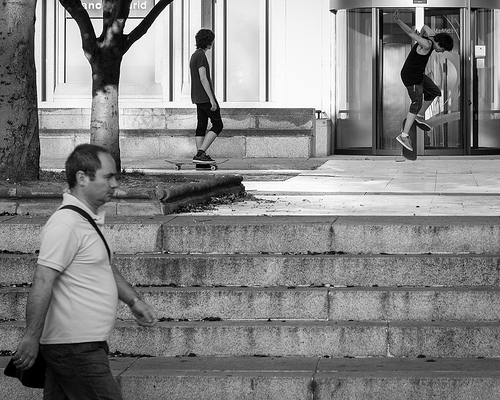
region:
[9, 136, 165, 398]
man in shirt is walking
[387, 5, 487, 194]
boy is jumping in front of door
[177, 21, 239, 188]
boy has one foot on skateboard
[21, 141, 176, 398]
man walking in front of tree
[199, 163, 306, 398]
steps up to sidewalk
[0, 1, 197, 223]
two trees in planter on sidewalk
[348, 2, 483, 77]
boy swinging arms behind him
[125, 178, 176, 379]
watch is on wrist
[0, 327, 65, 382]
ring on right hand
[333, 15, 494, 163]
revolving door into building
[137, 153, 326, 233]
leaves and dirt on sidewalk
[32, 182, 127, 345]
The light colored polo shirt the man is wearing.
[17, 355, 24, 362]
The ring on the man's finger.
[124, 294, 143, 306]
The watch on the man's wrist.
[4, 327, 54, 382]
The messenger bag behind the man's back.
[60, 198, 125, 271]
The messenger bag's strap across the man's chest.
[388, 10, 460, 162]
The boy jumping on the skateboard.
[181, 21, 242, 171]
The boy standing on the skateboard.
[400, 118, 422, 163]
The skateboard the boy is jumping off of.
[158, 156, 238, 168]
The skateboard the boy is standing on.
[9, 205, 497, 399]
The stairs leading up to where the skateboarders are.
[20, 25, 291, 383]
stairs separating two people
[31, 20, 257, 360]
teenager higher than man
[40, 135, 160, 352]
man carrying bag on shoulder strap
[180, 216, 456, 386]
blurred and dark markings on steps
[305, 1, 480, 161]
boy jumping with skateboard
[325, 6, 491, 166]
boy in front of revolving door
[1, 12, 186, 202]
trees growing in front of building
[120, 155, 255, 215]
corners of planting area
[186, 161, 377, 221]
dirt spilling over rim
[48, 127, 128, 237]
man with receding hairline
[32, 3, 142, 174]
A trunk of a tree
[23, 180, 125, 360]
man wearing a white polo shirt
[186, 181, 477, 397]
a concrete set of stairs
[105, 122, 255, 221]
Partition to separate the trees growing area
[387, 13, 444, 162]
boy jumps with skateboard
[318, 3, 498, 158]
boy in front of a revolving door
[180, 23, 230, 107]
a boy wearing a dark colored t-shirt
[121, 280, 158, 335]
A man wears a band on his wrist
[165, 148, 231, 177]
a foor rests on a skateboard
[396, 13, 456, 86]
jumping boy wears a black tank top